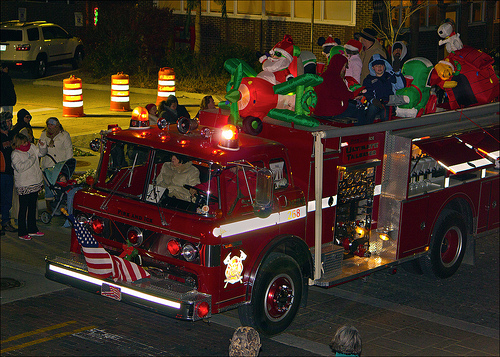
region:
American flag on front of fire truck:
[56, 206, 150, 287]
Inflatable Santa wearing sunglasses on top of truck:
[255, 38, 295, 87]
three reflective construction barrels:
[52, 69, 189, 111]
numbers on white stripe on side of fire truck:
[278, 208, 307, 223]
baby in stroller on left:
[36, 146, 93, 226]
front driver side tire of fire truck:
[250, 241, 300, 340]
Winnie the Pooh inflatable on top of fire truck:
[423, 57, 461, 88]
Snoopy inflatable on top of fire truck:
[434, 17, 467, 54]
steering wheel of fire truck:
[183, 180, 218, 207]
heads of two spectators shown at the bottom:
[218, 321, 378, 355]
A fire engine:
[39, 65, 447, 320]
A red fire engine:
[56, 80, 455, 308]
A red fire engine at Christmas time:
[57, 19, 460, 233]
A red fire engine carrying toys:
[68, 36, 481, 240]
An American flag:
[5, 192, 173, 305]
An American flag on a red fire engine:
[32, 162, 244, 324]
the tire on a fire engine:
[208, 221, 340, 340]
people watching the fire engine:
[10, 103, 188, 282]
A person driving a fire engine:
[109, 138, 215, 218]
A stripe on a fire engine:
[155, 179, 319, 262]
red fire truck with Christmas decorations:
[115, 48, 480, 299]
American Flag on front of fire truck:
[18, 215, 188, 306]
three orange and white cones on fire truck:
[55, 71, 193, 111]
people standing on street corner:
[5, 51, 102, 228]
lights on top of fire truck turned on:
[105, 90, 295, 187]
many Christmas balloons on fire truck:
[210, 37, 484, 119]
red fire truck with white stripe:
[114, 62, 485, 272]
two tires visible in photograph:
[254, 208, 485, 355]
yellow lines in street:
[7, 308, 84, 355]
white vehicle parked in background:
[5, 12, 107, 86]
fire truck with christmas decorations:
[77, 15, 498, 313]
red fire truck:
[52, 82, 497, 334]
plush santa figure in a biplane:
[219, 37, 324, 135]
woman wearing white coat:
[9, 130, 47, 241]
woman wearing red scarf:
[12, 131, 34, 159]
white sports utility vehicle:
[1, 16, 87, 73]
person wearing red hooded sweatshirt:
[316, 50, 371, 127]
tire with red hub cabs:
[245, 251, 311, 333]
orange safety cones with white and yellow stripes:
[53, 69, 134, 118]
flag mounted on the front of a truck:
[54, 202, 217, 328]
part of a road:
[416, 277, 464, 310]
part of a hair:
[341, 332, 361, 347]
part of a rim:
[266, 286, 290, 316]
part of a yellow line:
[51, 317, 86, 348]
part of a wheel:
[272, 255, 302, 302]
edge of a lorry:
[193, 225, 232, 288]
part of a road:
[128, 310, 169, 338]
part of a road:
[322, 67, 352, 131]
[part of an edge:
[118, 277, 183, 318]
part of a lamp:
[213, 120, 240, 160]